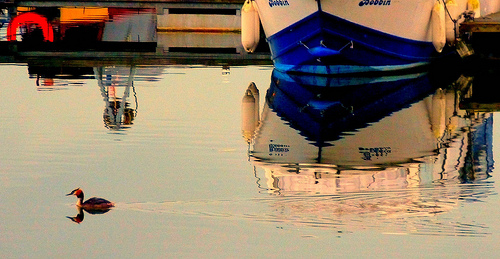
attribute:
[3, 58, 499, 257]
water — calm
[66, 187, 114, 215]
bird — black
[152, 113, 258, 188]
water — calm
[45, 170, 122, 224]
bird — black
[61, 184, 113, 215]
bird — black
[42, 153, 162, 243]
bird — black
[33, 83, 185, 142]
water — calm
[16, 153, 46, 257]
water — calm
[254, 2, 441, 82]
boat — blue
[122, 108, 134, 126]
girl — yellow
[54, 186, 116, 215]
birds — head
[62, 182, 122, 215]
bird — black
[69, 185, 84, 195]
spot — red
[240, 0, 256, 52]
bouy — white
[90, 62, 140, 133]
reflection — another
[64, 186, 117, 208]
bird — black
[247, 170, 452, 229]
water — calm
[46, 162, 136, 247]
bird — black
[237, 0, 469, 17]
boat — white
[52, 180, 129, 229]
bird — black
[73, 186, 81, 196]
spot — red